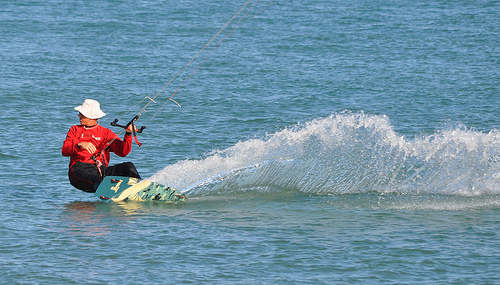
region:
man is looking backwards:
[76, 93, 101, 134]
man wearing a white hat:
[46, 88, 121, 133]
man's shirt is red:
[60, 122, 128, 163]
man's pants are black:
[57, 155, 158, 196]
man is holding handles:
[105, 110, 158, 150]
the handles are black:
[112, 108, 159, 145]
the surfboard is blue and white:
[99, 173, 186, 213]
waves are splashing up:
[154, 89, 496, 221]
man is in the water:
[9, 8, 474, 248]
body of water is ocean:
[11, 3, 474, 246]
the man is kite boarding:
[57, 79, 192, 214]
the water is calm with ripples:
[9, 3, 494, 282]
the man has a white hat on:
[71, 95, 107, 129]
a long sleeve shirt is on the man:
[59, 121, 134, 172]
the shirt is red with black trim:
[59, 121, 137, 169]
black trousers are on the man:
[68, 160, 144, 197]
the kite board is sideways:
[97, 173, 187, 213]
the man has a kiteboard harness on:
[57, 111, 157, 176]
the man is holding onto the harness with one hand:
[112, 104, 154, 151]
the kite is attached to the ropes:
[128, 0, 258, 138]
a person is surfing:
[49, 5, 321, 211]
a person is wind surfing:
[42, 6, 343, 215]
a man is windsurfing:
[51, 18, 263, 213]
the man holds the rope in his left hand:
[54, 17, 228, 209]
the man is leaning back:
[59, 86, 198, 212]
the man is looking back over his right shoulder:
[58, 89, 193, 209]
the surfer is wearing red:
[56, 91, 224, 209]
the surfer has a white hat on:
[56, 86, 212, 211]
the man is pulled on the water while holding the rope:
[55, 42, 390, 227]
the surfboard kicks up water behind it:
[91, 69, 496, 217]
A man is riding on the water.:
[47, 87, 199, 223]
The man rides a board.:
[80, 166, 196, 218]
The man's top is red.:
[52, 115, 147, 176]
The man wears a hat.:
[64, 88, 121, 125]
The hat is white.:
[67, 89, 126, 122]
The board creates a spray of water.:
[82, 112, 494, 225]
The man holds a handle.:
[76, 93, 166, 160]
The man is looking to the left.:
[47, 85, 155, 205]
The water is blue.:
[0, 2, 496, 90]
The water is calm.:
[0, 1, 499, 92]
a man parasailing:
[29, 31, 265, 281]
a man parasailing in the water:
[47, 30, 250, 270]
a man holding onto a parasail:
[27, 14, 264, 279]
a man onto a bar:
[40, 57, 246, 274]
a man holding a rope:
[16, 32, 317, 282]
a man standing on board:
[53, 60, 225, 271]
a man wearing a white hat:
[51, 47, 305, 260]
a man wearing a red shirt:
[39, 41, 219, 278]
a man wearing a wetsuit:
[24, 55, 228, 262]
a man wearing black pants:
[52, 52, 251, 251]